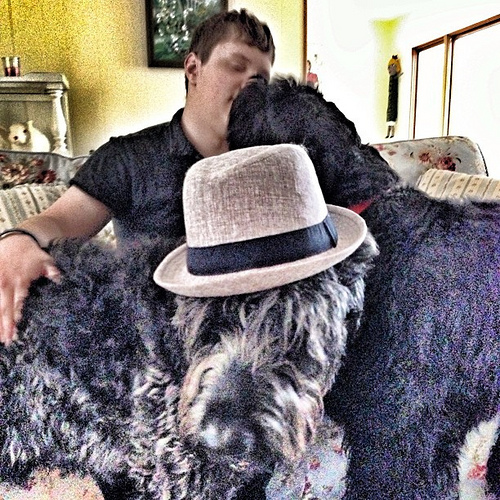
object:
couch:
[0, 134, 500, 242]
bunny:
[8, 121, 51, 152]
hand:
[0, 230, 61, 345]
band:
[0, 230, 40, 247]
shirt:
[68, 107, 207, 249]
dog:
[225, 74, 500, 500]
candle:
[4, 54, 20, 75]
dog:
[0, 141, 379, 500]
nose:
[213, 431, 248, 457]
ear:
[184, 51, 198, 85]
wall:
[0, 0, 305, 158]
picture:
[150, 0, 226, 68]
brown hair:
[185, 10, 276, 95]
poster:
[302, 57, 320, 89]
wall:
[309, 8, 390, 146]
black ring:
[185, 211, 337, 276]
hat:
[152, 142, 366, 299]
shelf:
[0, 72, 72, 157]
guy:
[0, 9, 276, 342]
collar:
[348, 183, 404, 214]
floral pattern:
[417, 151, 462, 172]